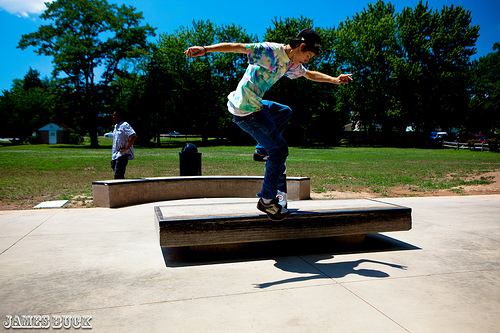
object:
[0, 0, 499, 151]
trees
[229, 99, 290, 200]
jeans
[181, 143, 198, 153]
top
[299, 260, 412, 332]
cracks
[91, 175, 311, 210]
concrete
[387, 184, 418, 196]
patche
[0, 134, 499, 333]
ground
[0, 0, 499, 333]
park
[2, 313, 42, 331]
james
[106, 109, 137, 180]
man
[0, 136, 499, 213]
grass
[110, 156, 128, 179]
pants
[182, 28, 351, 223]
boy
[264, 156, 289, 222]
skateboard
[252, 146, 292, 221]
feet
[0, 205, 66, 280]
cracks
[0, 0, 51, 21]
cloud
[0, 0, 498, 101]
sky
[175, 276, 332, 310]
cracks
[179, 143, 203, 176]
trash can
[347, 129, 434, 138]
flowers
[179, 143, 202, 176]
can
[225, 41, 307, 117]
colorful shirt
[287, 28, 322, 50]
hat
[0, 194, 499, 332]
pavement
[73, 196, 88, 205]
flowers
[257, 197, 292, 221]
shoes